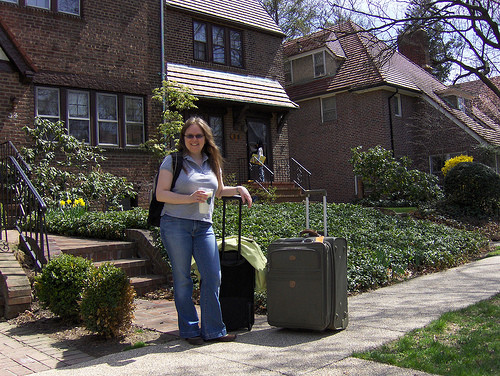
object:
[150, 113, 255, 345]
girl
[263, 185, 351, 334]
suitcase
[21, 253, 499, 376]
sidewalk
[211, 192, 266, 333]
suitcase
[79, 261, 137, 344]
bush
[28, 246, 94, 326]
bush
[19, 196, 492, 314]
ground cover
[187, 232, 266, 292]
sweater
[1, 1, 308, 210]
house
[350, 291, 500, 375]
grass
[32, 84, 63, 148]
window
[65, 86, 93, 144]
window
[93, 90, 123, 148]
window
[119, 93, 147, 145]
window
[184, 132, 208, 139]
sunglasses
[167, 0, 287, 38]
roof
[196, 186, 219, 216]
mug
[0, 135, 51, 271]
rail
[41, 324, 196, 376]
shadow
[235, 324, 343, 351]
shadow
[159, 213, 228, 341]
jeans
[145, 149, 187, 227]
backpack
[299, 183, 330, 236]
handle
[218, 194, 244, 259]
handle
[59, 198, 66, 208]
flowers